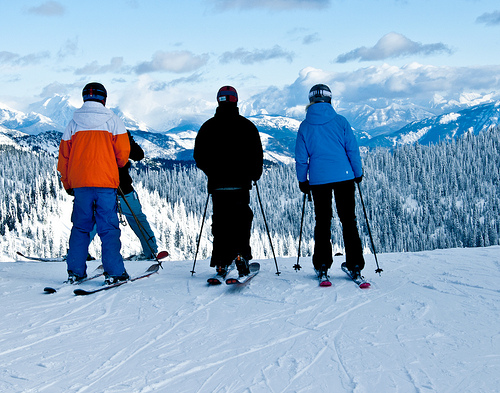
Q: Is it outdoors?
A: Yes, it is outdoors.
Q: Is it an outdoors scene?
A: Yes, it is outdoors.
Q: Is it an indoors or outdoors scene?
A: It is outdoors.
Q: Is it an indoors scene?
A: No, it is outdoors.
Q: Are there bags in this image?
A: No, there are no bags.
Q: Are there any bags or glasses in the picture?
A: No, there are no bags or glasses.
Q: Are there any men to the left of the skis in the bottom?
A: Yes, there is a man to the left of the skis.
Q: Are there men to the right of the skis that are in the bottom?
A: No, the man is to the left of the skis.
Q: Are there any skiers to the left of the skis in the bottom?
A: No, there is a man to the left of the skis.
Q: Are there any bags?
A: No, there are no bags.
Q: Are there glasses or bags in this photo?
A: No, there are no bags or glasses.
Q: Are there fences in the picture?
A: No, there are no fences.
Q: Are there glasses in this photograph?
A: No, there are no glasses.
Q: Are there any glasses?
A: No, there are no glasses.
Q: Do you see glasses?
A: No, there are no glasses.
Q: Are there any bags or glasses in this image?
A: No, there are no glasses or bags.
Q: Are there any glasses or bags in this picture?
A: No, there are no glasses or bags.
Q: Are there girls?
A: No, there are no girls.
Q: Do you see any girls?
A: No, there are no girls.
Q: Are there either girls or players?
A: No, there are no girls or players.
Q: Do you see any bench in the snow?
A: No, there is a man in the snow.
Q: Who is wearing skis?
A: The man is wearing skis.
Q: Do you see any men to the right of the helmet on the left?
A: Yes, there is a man to the right of the helmet.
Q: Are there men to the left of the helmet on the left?
A: No, the man is to the right of the helmet.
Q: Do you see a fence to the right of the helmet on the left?
A: No, there is a man to the right of the helmet.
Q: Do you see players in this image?
A: No, there are no players.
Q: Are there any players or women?
A: No, there are no players or women.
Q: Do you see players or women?
A: No, there are no players or women.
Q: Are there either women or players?
A: No, there are no players or women.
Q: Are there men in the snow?
A: Yes, there is a man in the snow.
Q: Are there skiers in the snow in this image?
A: No, there is a man in the snow.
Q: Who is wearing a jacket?
A: The man is wearing a jacket.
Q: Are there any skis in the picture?
A: Yes, there are skis.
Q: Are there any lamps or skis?
A: Yes, there are skis.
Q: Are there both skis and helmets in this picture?
A: Yes, there are both skis and a helmet.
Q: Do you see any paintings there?
A: No, there are no paintings.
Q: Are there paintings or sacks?
A: No, there are no paintings or sacks.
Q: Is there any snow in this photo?
A: Yes, there is snow.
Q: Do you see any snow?
A: Yes, there is snow.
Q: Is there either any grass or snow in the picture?
A: Yes, there is snow.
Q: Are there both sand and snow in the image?
A: No, there is snow but no sand.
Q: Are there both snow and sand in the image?
A: No, there is snow but no sand.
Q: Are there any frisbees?
A: No, there are no frisbees.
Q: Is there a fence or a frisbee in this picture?
A: No, there are no frisbees or fences.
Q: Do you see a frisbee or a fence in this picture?
A: No, there are no frisbees or fences.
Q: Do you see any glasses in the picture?
A: No, there are no glasses.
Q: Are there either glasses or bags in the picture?
A: No, there are no glasses or bags.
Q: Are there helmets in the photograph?
A: Yes, there is a helmet.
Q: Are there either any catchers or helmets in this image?
A: Yes, there is a helmet.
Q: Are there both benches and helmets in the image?
A: No, there is a helmet but no benches.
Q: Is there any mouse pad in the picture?
A: No, there are no mouse pads.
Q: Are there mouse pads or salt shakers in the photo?
A: No, there are no mouse pads or salt shakers.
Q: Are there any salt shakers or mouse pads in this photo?
A: No, there are no mouse pads or salt shakers.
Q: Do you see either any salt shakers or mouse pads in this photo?
A: No, there are no mouse pads or salt shakers.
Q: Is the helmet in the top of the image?
A: Yes, the helmet is in the top of the image.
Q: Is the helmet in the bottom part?
A: No, the helmet is in the top of the image.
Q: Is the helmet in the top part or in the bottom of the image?
A: The helmet is in the top of the image.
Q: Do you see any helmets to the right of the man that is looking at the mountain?
A: Yes, there is a helmet to the right of the man.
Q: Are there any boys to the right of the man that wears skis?
A: No, there is a helmet to the right of the man.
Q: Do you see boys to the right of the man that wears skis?
A: No, there is a helmet to the right of the man.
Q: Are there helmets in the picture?
A: Yes, there is a helmet.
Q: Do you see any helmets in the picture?
A: Yes, there is a helmet.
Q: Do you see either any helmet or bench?
A: Yes, there is a helmet.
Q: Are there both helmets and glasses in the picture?
A: No, there is a helmet but no glasses.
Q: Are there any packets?
A: No, there are no packets.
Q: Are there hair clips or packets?
A: No, there are no packets or hair clips.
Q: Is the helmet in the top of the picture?
A: Yes, the helmet is in the top of the image.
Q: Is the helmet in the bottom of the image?
A: No, the helmet is in the top of the image.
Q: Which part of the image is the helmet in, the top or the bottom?
A: The helmet is in the top of the image.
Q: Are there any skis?
A: Yes, there are skis.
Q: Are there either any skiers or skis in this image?
A: Yes, there are skis.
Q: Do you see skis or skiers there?
A: Yes, there are skis.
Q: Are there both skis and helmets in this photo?
A: Yes, there are both skis and a helmet.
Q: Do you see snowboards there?
A: No, there are no snowboards.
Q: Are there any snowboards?
A: No, there are no snowboards.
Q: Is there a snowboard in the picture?
A: No, there are no snowboards.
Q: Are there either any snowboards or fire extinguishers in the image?
A: No, there are no snowboards or fire extinguishers.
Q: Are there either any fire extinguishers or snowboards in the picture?
A: No, there are no snowboards or fire extinguishers.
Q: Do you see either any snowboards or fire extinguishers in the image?
A: No, there are no snowboards or fire extinguishers.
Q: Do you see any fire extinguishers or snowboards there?
A: No, there are no snowboards or fire extinguishers.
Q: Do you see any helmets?
A: Yes, there is a helmet.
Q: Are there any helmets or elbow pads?
A: Yes, there is a helmet.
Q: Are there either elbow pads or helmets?
A: Yes, there is a helmet.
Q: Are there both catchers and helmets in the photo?
A: No, there is a helmet but no catchers.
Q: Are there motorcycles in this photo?
A: No, there are no motorcycles.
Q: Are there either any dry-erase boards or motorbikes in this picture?
A: No, there are no motorbikes or dry-erase boards.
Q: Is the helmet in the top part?
A: Yes, the helmet is in the top of the image.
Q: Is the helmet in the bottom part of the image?
A: No, the helmet is in the top of the image.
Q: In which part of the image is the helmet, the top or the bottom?
A: The helmet is in the top of the image.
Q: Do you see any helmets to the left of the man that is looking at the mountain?
A: Yes, there is a helmet to the left of the man.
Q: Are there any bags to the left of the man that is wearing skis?
A: No, there is a helmet to the left of the man.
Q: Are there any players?
A: No, there are no players.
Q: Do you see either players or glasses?
A: No, there are no players or glasses.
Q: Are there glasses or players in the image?
A: No, there are no players or glasses.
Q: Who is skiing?
A: The man is skiing.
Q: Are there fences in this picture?
A: No, there are no fences.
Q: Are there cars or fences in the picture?
A: No, there are no fences or cars.